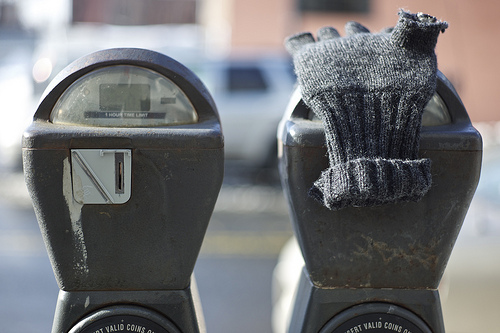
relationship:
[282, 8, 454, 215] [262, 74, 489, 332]
glove on meter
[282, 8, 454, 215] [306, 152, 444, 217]
glove has bottom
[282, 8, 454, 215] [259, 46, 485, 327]
glove on meter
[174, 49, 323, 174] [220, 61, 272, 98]
car has window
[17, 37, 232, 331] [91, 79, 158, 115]
meter has words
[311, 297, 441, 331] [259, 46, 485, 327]
dial on meter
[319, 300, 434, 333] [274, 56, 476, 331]
dial on meter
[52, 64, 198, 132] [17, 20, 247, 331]
dial on meter